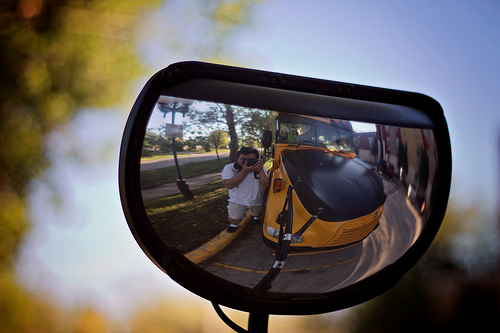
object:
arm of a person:
[258, 164, 269, 187]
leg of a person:
[249, 203, 265, 228]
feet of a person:
[227, 224, 247, 233]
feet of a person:
[250, 215, 266, 225]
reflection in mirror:
[294, 146, 329, 176]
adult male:
[221, 147, 274, 234]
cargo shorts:
[226, 200, 265, 220]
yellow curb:
[260, 110, 387, 252]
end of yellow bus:
[260, 152, 390, 252]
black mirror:
[261, 130, 274, 150]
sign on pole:
[164, 123, 186, 139]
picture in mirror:
[141, 94, 435, 292]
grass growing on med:
[140, 159, 222, 187]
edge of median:
[138, 169, 221, 200]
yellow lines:
[212, 237, 373, 273]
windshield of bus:
[276, 118, 355, 152]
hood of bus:
[282, 148, 389, 224]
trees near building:
[358, 128, 439, 218]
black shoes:
[226, 224, 240, 233]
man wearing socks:
[229, 223, 238, 228]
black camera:
[245, 158, 260, 165]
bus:
[261, 111, 388, 253]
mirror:
[116, 59, 457, 318]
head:
[236, 146, 261, 170]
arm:
[221, 164, 244, 189]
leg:
[225, 199, 250, 235]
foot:
[227, 223, 240, 233]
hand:
[242, 163, 259, 174]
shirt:
[220, 160, 269, 207]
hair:
[237, 147, 259, 161]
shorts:
[226, 201, 263, 220]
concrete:
[160, 187, 255, 274]